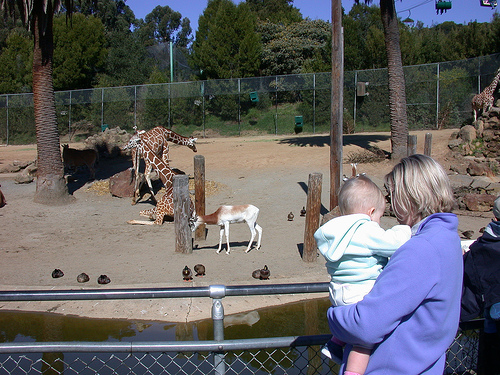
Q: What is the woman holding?
A: A baby.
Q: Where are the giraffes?
A: In the pen.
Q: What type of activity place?
A: Zoo.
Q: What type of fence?
A: Metal.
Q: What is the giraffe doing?
A: Sitting.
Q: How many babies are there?
A: One.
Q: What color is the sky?
A: Blue.